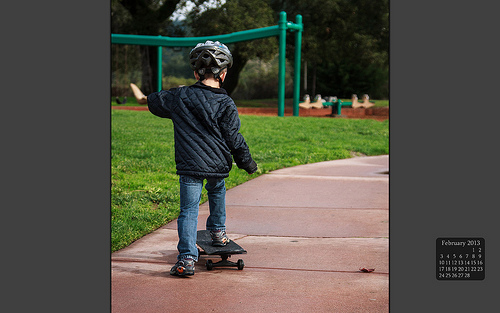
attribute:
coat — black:
[149, 84, 254, 178]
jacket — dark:
[140, 86, 254, 178]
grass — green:
[113, 106, 387, 253]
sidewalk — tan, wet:
[116, 155, 390, 311]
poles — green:
[278, 12, 303, 112]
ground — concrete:
[226, 141, 378, 302]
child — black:
[170, 30, 245, 121]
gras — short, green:
[249, 99, 379, 185]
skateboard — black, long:
[189, 221, 250, 280]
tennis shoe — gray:
[163, 240, 204, 286]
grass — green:
[249, 96, 354, 198]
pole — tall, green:
[273, 9, 294, 134]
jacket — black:
[159, 96, 254, 179]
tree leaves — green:
[205, 3, 262, 33]